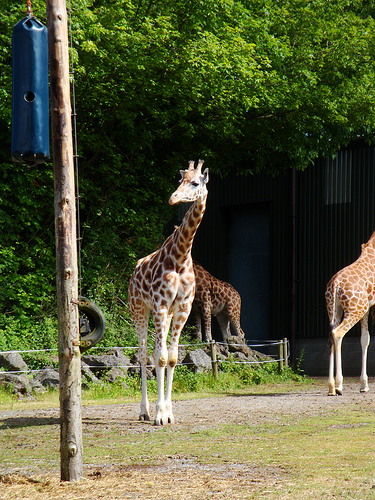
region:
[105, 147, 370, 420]
three giraffes in an enclosure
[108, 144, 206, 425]
giraffe standing in the middle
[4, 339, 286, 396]
fence behind the giraffe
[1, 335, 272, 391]
gray rocks behind the giraffe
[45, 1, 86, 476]
wood pole with blue object hanging from it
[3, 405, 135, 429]
giraffe's shadow on the ground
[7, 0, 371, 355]
trees behind the giraffe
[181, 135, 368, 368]
building on the right side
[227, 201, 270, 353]
door of the building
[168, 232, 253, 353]
giraffe grazing from trees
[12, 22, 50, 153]
blue bag on pole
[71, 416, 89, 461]
pole is tall and wooden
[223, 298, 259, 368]
giraffe with bent neck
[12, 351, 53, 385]
wire fence behind giraffe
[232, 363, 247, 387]
bright green grass by giraffe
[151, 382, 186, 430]
giraffe has white legs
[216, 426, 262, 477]
grass is green and brown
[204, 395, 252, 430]
worn path in grass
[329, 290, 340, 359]
giraffe has long thin tail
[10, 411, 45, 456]
shadow from tall giraffe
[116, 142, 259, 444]
the girrafe is tall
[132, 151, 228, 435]
the girrafe is standing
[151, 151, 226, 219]
the girrafe has horns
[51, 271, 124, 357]
the tube is black in colour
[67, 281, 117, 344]
the tube is on the post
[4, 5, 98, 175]
the bag is blue in colour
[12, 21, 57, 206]
the bag is made of leather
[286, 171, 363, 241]
the wall is made of iron sheets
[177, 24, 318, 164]
the tree is green in colour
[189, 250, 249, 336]
the girrafe is feeding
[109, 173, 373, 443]
three giraffes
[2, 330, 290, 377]
fencing around the rocks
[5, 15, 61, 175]
blue bag hanging from the pole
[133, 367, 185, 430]
bottom of giraffe's legs are white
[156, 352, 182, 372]
brown spots on the knees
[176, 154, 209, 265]
giraffe has a long neck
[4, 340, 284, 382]
rocks on the other side of fence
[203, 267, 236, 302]
giraffe is brown and white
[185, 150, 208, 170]
giraffe has knubs on his head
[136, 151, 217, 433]
giraffe standing near the pole